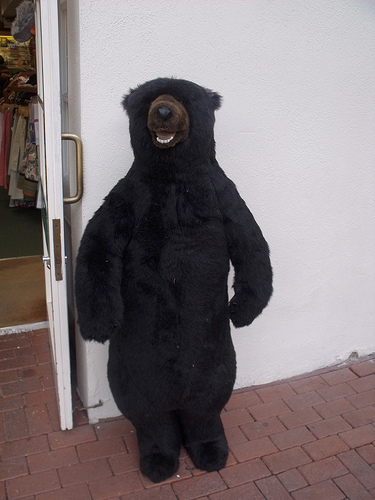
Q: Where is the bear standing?
A: Outside a door.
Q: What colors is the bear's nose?
A: Brown and black.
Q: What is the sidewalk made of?
A: Red brick.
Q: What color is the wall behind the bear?
A: White.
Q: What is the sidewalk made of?
A: Brick.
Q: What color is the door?
A: White.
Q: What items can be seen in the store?
A: Clothes.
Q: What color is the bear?
A: Black.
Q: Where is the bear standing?
A: By the door.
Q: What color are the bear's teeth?
A: White.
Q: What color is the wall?
A: White.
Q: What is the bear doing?
A: Standing.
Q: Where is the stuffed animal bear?
A: On the bricks.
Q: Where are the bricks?
A: On the ground.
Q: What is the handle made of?
A: Metal.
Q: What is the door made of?
A: Wood.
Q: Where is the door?
A: On the building.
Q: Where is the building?
A: Behind the bear.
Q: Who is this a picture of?
A: A bear.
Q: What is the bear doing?
A: Standing.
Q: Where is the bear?
A: In front of a wall.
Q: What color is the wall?
A: White.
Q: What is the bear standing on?
A: Bricks.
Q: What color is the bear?
A: Black.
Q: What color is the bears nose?
A: Black.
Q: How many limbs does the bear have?
A: Four.